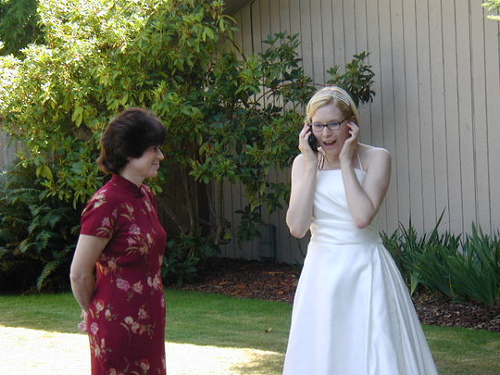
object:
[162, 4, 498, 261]
fence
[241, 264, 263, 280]
leaves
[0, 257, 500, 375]
ground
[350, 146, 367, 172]
strap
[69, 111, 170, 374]
mother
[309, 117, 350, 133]
eyeglasses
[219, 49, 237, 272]
bamboo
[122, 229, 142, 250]
flowers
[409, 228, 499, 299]
garden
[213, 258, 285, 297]
mulch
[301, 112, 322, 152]
phone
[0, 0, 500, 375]
yard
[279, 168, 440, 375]
dress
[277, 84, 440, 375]
girl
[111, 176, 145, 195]
collar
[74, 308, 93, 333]
hands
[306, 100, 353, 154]
girl`s face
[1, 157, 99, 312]
bushes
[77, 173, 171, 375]
dress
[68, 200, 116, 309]
arms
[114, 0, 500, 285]
house